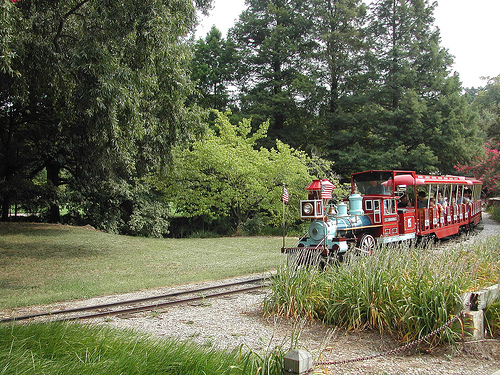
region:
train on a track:
[297, 162, 489, 262]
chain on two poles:
[293, 299, 483, 372]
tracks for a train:
[71, 276, 258, 315]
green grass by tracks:
[23, 246, 231, 278]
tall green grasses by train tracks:
[311, 258, 443, 329]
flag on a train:
[316, 177, 337, 206]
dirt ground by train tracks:
[171, 309, 274, 342]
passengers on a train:
[426, 191, 481, 212]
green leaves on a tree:
[181, 107, 285, 229]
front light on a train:
[299, 197, 326, 222]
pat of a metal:
[274, 325, 306, 370]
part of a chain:
[368, 339, 387, 359]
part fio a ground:
[229, 300, 268, 345]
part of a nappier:
[293, 238, 344, 287]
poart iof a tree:
[135, 95, 199, 193]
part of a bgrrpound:
[213, 288, 248, 331]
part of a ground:
[191, 266, 248, 330]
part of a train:
[356, 174, 403, 233]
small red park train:
[273, 162, 485, 273]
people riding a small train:
[399, 170, 481, 244]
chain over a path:
[304, 301, 474, 366]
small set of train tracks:
[6, 244, 294, 350]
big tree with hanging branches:
[1, 6, 176, 241]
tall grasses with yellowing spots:
[270, 225, 447, 355]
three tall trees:
[228, 1, 454, 227]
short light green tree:
[148, 111, 319, 246]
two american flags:
[272, 180, 333, 250]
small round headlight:
[296, 197, 322, 216]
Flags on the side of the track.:
[276, 177, 336, 259]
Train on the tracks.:
[269, 159, 496, 268]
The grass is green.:
[56, 236, 180, 278]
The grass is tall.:
[28, 342, 153, 372]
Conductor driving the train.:
[356, 169, 399, 204]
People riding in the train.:
[409, 173, 485, 221]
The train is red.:
[361, 165, 496, 247]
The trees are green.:
[108, 35, 357, 200]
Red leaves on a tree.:
[448, 145, 498, 209]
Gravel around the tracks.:
[114, 275, 224, 328]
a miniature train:
[266, 132, 484, 275]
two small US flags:
[261, 172, 335, 207]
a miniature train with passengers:
[288, 155, 492, 274]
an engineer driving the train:
[353, 170, 385, 211]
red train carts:
[416, 167, 468, 251]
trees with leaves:
[1, 100, 196, 230]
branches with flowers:
[480, 140, 498, 171]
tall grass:
[353, 257, 402, 327]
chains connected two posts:
[293, 304, 497, 374]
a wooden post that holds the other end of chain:
[278, 348, 320, 373]